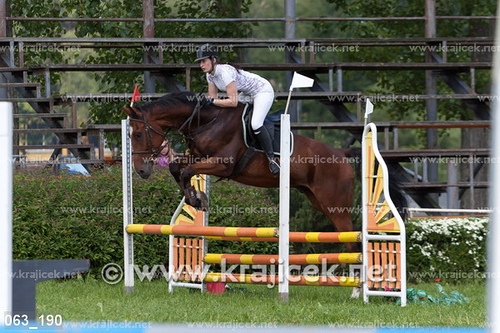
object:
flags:
[281, 69, 314, 114]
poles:
[277, 116, 291, 294]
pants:
[248, 79, 274, 129]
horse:
[124, 90, 409, 257]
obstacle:
[118, 110, 409, 307]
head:
[194, 42, 219, 73]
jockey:
[203, 64, 274, 135]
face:
[185, 38, 230, 80]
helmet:
[193, 44, 216, 63]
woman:
[186, 49, 283, 174]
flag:
[128, 85, 140, 103]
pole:
[128, 100, 136, 110]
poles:
[120, 113, 135, 285]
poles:
[126, 223, 279, 238]